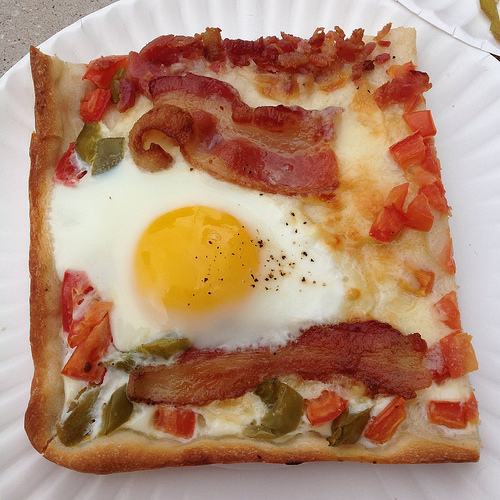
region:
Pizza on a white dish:
[6, 9, 499, 484]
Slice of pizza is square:
[11, 22, 494, 475]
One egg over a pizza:
[48, 149, 352, 352]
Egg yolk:
[127, 196, 270, 323]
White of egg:
[58, 158, 250, 209]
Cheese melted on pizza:
[286, 56, 450, 340]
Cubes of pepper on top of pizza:
[367, 100, 456, 248]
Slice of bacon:
[106, 56, 351, 203]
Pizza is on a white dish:
[9, 24, 497, 476]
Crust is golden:
[11, 35, 490, 480]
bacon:
[149, 340, 491, 400]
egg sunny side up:
[89, 171, 330, 348]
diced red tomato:
[379, 118, 451, 288]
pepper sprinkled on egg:
[165, 222, 347, 296]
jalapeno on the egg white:
[257, 382, 317, 450]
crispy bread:
[31, 111, 89, 458]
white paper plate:
[39, 0, 286, 44]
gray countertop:
[8, 3, 93, 63]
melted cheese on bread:
[286, 67, 409, 270]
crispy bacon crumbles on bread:
[191, 29, 428, 92]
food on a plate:
[17, 41, 484, 468]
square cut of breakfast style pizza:
[20, 50, 478, 482]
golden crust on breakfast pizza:
[16, 244, 218, 481]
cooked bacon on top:
[121, 319, 403, 406]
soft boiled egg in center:
[84, 172, 350, 342]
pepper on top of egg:
[196, 181, 326, 300]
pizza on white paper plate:
[15, 8, 140, 90]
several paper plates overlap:
[402, 0, 496, 76]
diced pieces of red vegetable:
[370, 94, 457, 261]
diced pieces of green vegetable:
[55, 91, 132, 190]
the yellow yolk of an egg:
[128, 202, 265, 326]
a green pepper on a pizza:
[53, 382, 102, 445]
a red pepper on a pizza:
[152, 400, 198, 442]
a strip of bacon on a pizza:
[122, 315, 434, 408]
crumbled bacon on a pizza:
[186, 16, 394, 96]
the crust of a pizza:
[21, 44, 52, 447]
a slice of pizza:
[27, 23, 485, 478]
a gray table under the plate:
[0, 0, 117, 82]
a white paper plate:
[1, 0, 498, 497]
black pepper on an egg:
[256, 208, 326, 293]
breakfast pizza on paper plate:
[20, 20, 480, 470]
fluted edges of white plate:
[90, 0, 480, 60]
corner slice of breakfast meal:
[20, 35, 485, 495]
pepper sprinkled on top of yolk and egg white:
[120, 187, 330, 327]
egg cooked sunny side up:
[61, 166, 361, 357]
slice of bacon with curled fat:
[120, 70, 345, 195]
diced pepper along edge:
[70, 380, 460, 445]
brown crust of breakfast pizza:
[71, 430, 481, 475]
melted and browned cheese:
[300, 85, 450, 345]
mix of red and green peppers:
[133, 376, 404, 437]